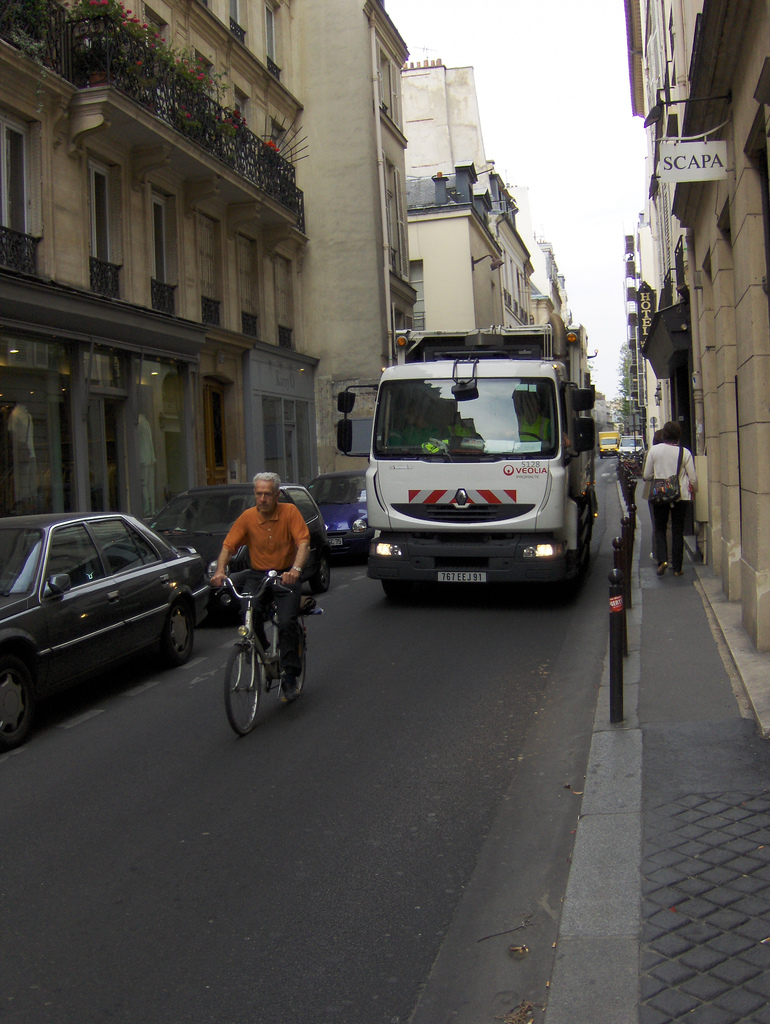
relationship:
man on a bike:
[204, 457, 322, 605] [175, 551, 327, 761]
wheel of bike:
[223, 638, 262, 737] [196, 547, 348, 743]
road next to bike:
[0, 427, 770, 1024] [192, 572, 343, 754]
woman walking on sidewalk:
[643, 421, 697, 579] [629, 544, 743, 766]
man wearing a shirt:
[211, 471, 312, 699] [239, 501, 311, 578]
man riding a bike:
[203, 461, 337, 712] [175, 540, 333, 740]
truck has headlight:
[329, 350, 620, 621] [360, 513, 422, 574]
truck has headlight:
[329, 350, 620, 621] [504, 522, 574, 561]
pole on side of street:
[594, 554, 658, 757] [542, 638, 738, 941]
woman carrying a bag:
[629, 401, 714, 612] [636, 424, 693, 512]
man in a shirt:
[203, 461, 337, 712] [202, 498, 315, 586]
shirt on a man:
[211, 499, 323, 592] [192, 443, 322, 700]